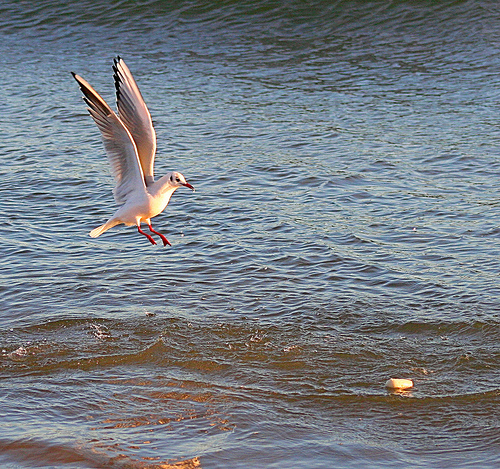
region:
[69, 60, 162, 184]
the two extended wings of the bird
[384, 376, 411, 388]
an unrecognizable object floating on the water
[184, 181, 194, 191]
the red bill of the bird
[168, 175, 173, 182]
a black spot on the head of the bird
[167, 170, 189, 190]
the head of the bird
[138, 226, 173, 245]
the two legs of the bird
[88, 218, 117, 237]
the tail of the bird is white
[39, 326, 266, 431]
some waves on the water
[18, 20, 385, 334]
the bird is flying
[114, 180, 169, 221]
the pumage of the bird is white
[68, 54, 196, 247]
A white, grey and black bird with bright orange legs.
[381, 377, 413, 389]
A chunk of white in the water.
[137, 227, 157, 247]
Bright red right leg of a bird.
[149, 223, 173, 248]
Bright red left leg of a bird.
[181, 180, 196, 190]
Red and black beak on a bird.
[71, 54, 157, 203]
White, grey and black wings of a bird.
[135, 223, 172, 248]
Red long legs of a bird.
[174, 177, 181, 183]
Black round eye of a bird.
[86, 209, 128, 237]
White tail feathers on a bird.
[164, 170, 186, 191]
White head of a bird.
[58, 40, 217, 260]
bird flying in the air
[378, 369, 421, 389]
object floating in the water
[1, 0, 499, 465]
a body of water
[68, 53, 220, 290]
bird flying over the water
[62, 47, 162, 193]
a pair of long wings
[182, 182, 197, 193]
beak sticking off the face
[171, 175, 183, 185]
dark eye on the side of the face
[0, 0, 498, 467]
small ripples in the water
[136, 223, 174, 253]
a pair of legs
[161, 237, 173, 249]
orange webbed foot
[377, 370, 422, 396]
something floating in the water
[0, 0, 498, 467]
large body of water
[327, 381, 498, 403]
small ripple in the water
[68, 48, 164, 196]
a pair of wings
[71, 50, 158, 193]
large white wings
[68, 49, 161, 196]
wings sticking straight up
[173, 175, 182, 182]
black eye on the side of the head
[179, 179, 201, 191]
pointy beak sticking off the face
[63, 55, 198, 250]
bird flying through air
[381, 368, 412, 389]
piece of food floating in water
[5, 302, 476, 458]
ripples in the water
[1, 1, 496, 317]
small waves in the water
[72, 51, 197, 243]
bird has both wings up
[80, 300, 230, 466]
orange light reflecting off the water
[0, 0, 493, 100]
shadow in the back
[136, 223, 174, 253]
legs are orange on bird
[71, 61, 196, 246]
birds wings are mostly white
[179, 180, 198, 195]
bird's beak is orange